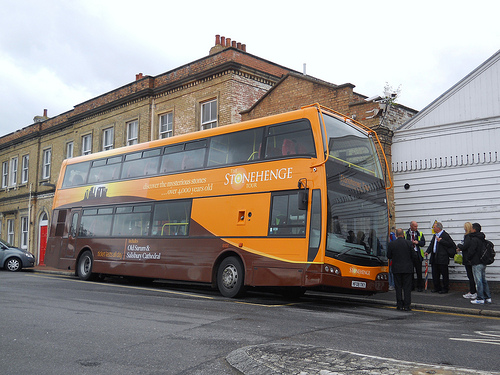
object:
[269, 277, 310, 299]
tire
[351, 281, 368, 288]
number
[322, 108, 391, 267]
front glass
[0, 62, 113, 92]
clouds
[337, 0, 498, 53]
clouds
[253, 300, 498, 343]
road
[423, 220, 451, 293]
man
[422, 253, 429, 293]
umbrella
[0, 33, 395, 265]
brick building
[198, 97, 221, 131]
white windows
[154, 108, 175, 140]
white windows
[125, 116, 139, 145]
white windows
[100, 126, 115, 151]
white windows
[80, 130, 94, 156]
white windows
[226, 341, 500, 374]
island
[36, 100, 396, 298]
stone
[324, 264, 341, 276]
light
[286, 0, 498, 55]
sky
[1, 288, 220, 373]
road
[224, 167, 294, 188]
letters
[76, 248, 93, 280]
tire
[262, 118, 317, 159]
window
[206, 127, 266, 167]
window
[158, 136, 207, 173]
window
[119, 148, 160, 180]
window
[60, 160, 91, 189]
window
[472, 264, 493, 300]
jeans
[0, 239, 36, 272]
car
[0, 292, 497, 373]
street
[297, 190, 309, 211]
mirror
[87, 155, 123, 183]
windows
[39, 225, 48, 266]
red door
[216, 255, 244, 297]
front wheel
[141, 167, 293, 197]
letters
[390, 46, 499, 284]
building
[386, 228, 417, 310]
people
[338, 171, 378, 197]
route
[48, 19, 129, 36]
sky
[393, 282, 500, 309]
sidewalk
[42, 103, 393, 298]
bus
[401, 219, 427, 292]
people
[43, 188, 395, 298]
lower level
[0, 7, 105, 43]
clouds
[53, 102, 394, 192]
top level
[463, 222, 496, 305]
man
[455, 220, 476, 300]
people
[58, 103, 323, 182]
part